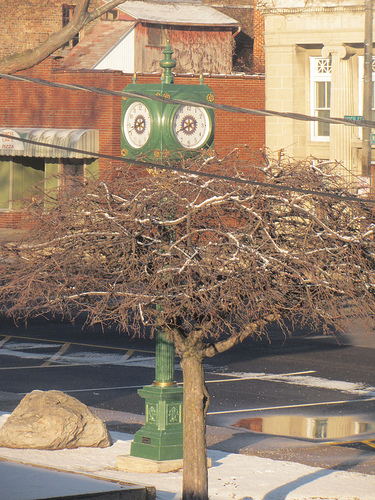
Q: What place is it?
A: It is a street.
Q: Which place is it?
A: It is a street.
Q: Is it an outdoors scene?
A: Yes, it is outdoors.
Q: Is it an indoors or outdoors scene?
A: It is outdoors.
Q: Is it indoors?
A: No, it is outdoors.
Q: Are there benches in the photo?
A: No, there are no benches.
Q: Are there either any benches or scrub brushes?
A: No, there are no benches or scrub brushes.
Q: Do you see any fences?
A: No, there are no fences.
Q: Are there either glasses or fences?
A: No, there are no fences or glasses.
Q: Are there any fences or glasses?
A: No, there are no fences or glasses.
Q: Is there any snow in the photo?
A: Yes, there is snow.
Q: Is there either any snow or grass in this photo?
A: Yes, there is snow.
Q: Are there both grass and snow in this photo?
A: No, there is snow but no grass.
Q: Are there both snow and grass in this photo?
A: No, there is snow but no grass.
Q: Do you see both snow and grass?
A: No, there is snow but no grass.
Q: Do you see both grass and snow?
A: No, there is snow but no grass.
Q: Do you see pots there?
A: No, there are no pots.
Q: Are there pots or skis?
A: No, there are no pots or skis.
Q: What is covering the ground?
A: The snow is covering the ground.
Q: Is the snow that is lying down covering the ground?
A: Yes, the snow is covering the ground.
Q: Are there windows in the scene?
A: Yes, there is a window.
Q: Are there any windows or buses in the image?
A: Yes, there is a window.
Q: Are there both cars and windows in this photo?
A: No, there is a window but no cars.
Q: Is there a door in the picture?
A: No, there are no doors.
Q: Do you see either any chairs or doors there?
A: No, there are no doors or chairs.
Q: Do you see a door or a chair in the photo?
A: No, there are no doors or chairs.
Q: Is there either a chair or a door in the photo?
A: No, there are no doors or chairs.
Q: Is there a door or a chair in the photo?
A: No, there are no doors or chairs.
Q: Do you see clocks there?
A: Yes, there is a clock.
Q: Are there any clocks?
A: Yes, there is a clock.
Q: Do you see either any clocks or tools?
A: Yes, there is a clock.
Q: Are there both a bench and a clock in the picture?
A: No, there is a clock but no benches.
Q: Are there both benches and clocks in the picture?
A: No, there is a clock but no benches.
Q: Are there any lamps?
A: No, there are no lamps.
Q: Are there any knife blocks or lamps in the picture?
A: No, there are no lamps or knife blocks.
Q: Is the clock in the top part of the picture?
A: Yes, the clock is in the top of the image.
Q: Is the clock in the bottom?
A: No, the clock is in the top of the image.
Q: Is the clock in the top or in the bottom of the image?
A: The clock is in the top of the image.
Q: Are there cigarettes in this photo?
A: No, there are no cigarettes.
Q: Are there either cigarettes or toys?
A: No, there are no cigarettes or toys.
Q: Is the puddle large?
A: Yes, the puddle is large.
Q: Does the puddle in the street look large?
A: Yes, the puddle is large.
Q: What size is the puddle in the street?
A: The puddle is large.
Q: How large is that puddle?
A: The puddle is large.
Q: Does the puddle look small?
A: No, the puddle is large.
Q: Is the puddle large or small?
A: The puddle is large.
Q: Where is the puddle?
A: The puddle is in the street.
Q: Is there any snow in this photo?
A: Yes, there is snow.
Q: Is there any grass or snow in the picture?
A: Yes, there is snow.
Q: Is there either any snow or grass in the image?
A: Yes, there is snow.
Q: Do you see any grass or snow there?
A: Yes, there is snow.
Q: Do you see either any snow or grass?
A: Yes, there is snow.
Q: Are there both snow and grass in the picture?
A: No, there is snow but no grass.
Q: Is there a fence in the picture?
A: No, there are no fences.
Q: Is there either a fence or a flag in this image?
A: No, there are no fences or flags.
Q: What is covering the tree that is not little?
A: The snow is covering the tree.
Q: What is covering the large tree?
A: The snow is covering the tree.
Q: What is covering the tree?
A: The snow is covering the tree.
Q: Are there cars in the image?
A: No, there are no cars.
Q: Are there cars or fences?
A: No, there are no cars or fences.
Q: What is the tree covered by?
A: The tree is covered by the snow.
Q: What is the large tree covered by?
A: The tree is covered by the snow.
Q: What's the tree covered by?
A: The tree is covered by the snow.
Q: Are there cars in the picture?
A: No, there are no cars.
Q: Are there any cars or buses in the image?
A: No, there are no cars or buses.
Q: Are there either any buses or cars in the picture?
A: No, there are no cars or buses.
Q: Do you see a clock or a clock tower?
A: Yes, there is a clock.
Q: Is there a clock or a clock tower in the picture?
A: Yes, there is a clock.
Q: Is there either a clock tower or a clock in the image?
A: Yes, there is a clock.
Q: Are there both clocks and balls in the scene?
A: No, there is a clock but no balls.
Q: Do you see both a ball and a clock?
A: No, there is a clock but no balls.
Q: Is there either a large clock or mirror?
A: Yes, there is a large clock.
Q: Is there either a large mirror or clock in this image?
A: Yes, there is a large clock.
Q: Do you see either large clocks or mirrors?
A: Yes, there is a large clock.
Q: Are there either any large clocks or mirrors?
A: Yes, there is a large clock.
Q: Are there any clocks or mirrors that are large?
A: Yes, the clock is large.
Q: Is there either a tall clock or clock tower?
A: Yes, there is a tall clock.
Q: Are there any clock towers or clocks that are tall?
A: Yes, the clock is tall.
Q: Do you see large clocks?
A: Yes, there is a large clock.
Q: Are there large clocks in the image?
A: Yes, there is a large clock.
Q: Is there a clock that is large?
A: Yes, there is a clock that is large.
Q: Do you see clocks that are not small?
A: Yes, there is a large clock.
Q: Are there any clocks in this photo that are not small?
A: Yes, there is a large clock.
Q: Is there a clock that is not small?
A: Yes, there is a large clock.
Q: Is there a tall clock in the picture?
A: Yes, there is a tall clock.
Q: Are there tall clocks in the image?
A: Yes, there is a tall clock.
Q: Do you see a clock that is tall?
A: Yes, there is a clock that is tall.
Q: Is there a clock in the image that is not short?
A: Yes, there is a tall clock.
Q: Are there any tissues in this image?
A: No, there are no tissues.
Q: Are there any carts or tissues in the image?
A: No, there are no tissues or carts.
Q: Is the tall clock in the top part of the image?
A: Yes, the clock is in the top of the image.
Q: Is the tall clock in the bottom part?
A: No, the clock is in the top of the image.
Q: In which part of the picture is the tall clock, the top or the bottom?
A: The clock is in the top of the image.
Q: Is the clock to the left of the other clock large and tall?
A: Yes, the clock is large and tall.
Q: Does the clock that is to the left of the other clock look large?
A: Yes, the clock is large.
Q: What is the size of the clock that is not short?
A: The clock is large.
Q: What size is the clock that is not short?
A: The clock is large.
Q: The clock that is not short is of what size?
A: The clock is large.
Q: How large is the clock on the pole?
A: The clock is large.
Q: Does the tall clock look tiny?
A: No, the clock is large.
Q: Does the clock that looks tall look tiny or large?
A: The clock is large.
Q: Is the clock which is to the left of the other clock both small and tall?
A: No, the clock is tall but large.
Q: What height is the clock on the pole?
A: The clock is tall.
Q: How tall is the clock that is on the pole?
A: The clock is tall.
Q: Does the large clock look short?
A: No, the clock is tall.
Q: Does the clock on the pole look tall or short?
A: The clock is tall.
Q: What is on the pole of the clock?
A: The clock is on the pole.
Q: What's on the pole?
A: The clock is on the pole.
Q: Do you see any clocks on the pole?
A: Yes, there is a clock on the pole.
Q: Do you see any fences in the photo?
A: No, there are no fences.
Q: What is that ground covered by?
A: The ground is covered by the snow.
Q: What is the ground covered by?
A: The ground is covered by the snow.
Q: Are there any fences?
A: No, there are no fences.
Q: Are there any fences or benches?
A: No, there are no fences or benches.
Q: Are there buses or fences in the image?
A: No, there are no fences or buses.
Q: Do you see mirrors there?
A: No, there are no mirrors.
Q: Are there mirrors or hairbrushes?
A: No, there are no mirrors or hairbrushes.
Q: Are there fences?
A: No, there are no fences.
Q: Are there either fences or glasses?
A: No, there are no fences or glasses.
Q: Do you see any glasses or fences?
A: No, there are no fences or glasses.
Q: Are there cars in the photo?
A: No, there are no cars.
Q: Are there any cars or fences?
A: No, there are no cars or fences.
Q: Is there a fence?
A: No, there are no fences.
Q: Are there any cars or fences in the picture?
A: No, there are no fences or cars.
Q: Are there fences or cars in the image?
A: No, there are no fences or cars.